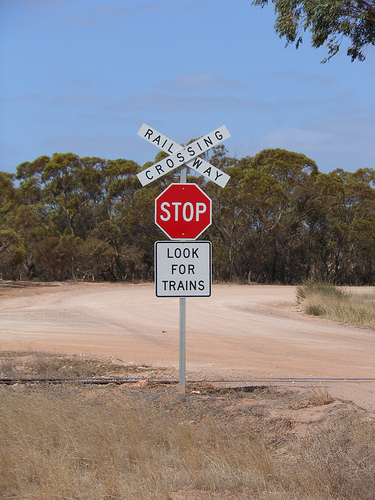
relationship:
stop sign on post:
[150, 182, 215, 245] [173, 171, 193, 406]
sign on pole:
[152, 240, 213, 297] [179, 166, 185, 395]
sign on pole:
[152, 240, 213, 297] [174, 162, 191, 389]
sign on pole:
[152, 240, 213, 297] [178, 295, 186, 395]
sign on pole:
[152, 240, 213, 297] [179, 296, 186, 389]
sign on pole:
[150, 244, 216, 301] [176, 297, 187, 363]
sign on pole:
[152, 240, 213, 297] [179, 296, 184, 393]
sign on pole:
[152, 240, 213, 297] [177, 295, 187, 395]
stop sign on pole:
[154, 182, 213, 242] [179, 166, 185, 395]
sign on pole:
[134, 122, 234, 186] [179, 166, 185, 395]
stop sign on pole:
[154, 182, 213, 242] [178, 143, 186, 392]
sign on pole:
[152, 240, 213, 297] [177, 169, 186, 393]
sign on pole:
[152, 240, 213, 297] [177, 295, 186, 394]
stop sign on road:
[154, 182, 213, 242] [5, 286, 370, 410]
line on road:
[217, 288, 372, 445] [11, 277, 372, 414]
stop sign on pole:
[154, 182, 213, 242] [174, 297, 195, 395]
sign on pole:
[152, 240, 213, 297] [174, 297, 195, 395]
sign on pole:
[134, 122, 234, 186] [174, 297, 195, 395]